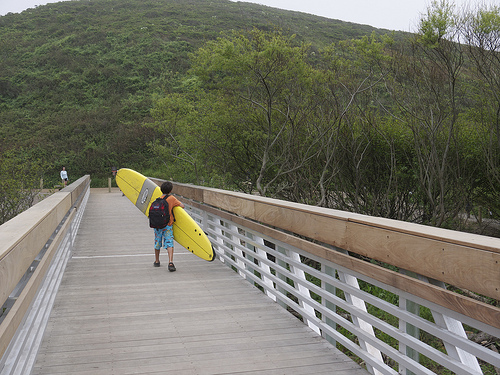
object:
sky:
[351, 1, 427, 32]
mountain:
[0, 0, 497, 176]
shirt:
[156, 194, 181, 226]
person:
[60, 167, 70, 188]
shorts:
[150, 225, 175, 252]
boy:
[108, 161, 214, 286]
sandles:
[167, 262, 176, 272]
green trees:
[208, 36, 276, 198]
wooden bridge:
[0, 174, 500, 373]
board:
[254, 201, 348, 250]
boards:
[215, 333, 254, 340]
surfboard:
[113, 166, 215, 262]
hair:
[160, 181, 174, 194]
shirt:
[60, 170, 68, 178]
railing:
[214, 190, 500, 374]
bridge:
[0, 174, 497, 375]